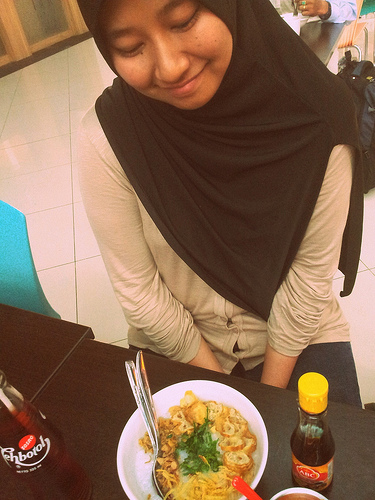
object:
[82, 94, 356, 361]
shirt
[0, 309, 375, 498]
black table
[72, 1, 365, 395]
girl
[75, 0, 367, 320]
burka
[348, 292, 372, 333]
tile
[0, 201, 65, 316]
empty chair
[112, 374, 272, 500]
bowl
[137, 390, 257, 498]
food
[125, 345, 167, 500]
spoon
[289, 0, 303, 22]
spoon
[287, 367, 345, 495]
bottle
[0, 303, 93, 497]
table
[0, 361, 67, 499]
soda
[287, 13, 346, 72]
table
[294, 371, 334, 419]
cover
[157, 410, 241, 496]
vegetables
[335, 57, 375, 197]
backpack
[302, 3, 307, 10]
ring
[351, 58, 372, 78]
handle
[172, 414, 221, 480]
green garnish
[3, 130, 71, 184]
tiles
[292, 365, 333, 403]
bottle top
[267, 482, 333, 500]
plate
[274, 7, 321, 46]
bowl